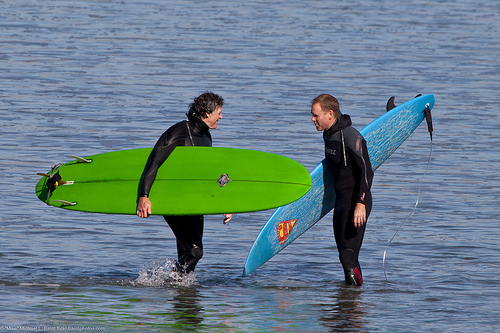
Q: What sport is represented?
A: Surfing.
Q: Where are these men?
A: The ocean.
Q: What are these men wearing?
A: Wetsuits.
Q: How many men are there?
A: Two.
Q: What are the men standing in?
A: Water.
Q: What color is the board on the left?
A: Green.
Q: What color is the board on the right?
A: Blue.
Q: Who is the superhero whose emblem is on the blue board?
A: Superman.